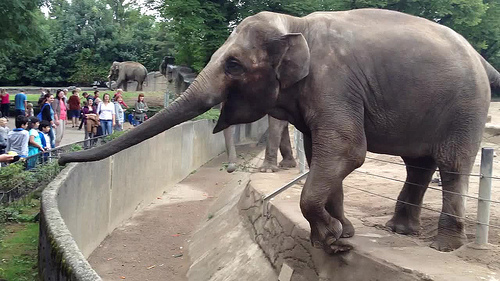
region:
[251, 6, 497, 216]
this is an elephant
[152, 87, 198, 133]
this is the trunk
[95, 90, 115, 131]
this is a lady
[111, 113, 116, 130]
the lady is light skinned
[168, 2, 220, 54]
this is a tree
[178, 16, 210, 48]
the tree has green leaves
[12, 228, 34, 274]
this is grass area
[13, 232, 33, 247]
the grass is green in color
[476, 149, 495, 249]
this is a pole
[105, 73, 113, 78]
this is the tusk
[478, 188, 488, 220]
the fence is wired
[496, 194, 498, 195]
the fence is wired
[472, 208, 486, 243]
the fence is wired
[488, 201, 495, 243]
the fence is wired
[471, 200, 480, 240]
the fence is wired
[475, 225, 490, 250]
the fence is wired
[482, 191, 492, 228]
the fence is wired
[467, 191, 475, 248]
the fence is wired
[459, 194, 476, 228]
the fence is wired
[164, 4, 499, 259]
elephant climbing over fence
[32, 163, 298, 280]
dry moat around elephant enclosure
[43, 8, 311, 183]
elephant reaching out trunk towards people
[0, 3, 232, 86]
thick foilage around elephant pens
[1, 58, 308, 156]
zoo visitors watching an elephant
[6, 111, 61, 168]
young black haired boys by the fence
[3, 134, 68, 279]
shurbs and weeds growing on wall and fence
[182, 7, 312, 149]
elephant opening it's mouth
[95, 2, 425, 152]
two elephants at a zoo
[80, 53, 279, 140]
women standing and watching an elephant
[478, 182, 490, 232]
the fence are wired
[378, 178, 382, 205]
the fence are wired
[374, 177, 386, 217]
the fence are wired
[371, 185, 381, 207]
the fence are wired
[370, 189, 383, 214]
the fence are wired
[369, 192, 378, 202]
the fence are wired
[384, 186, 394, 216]
the fence are wired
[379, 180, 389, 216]
the fence are wired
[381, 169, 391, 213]
the fence are wired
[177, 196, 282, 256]
large gray stone pit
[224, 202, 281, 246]
broken stones in pit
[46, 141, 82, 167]
black tip of elephant's trunk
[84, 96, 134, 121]
long sleeve white shirt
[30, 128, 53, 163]
girl's hand resting on small wall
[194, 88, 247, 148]
open mouth on elephant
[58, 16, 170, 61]
large cluster of green trees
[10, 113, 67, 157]
children standing in front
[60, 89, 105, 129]
woman holdig brown coat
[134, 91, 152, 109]
long brown hair on woman